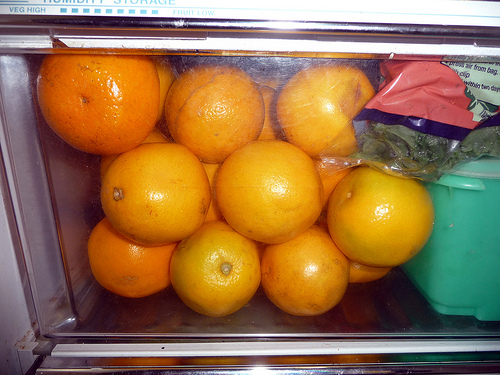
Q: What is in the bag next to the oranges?
A: Greens.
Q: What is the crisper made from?
A: Plastic.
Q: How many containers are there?
A: One.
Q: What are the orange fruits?
A: Oranges.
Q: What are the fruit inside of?
A: A crisper.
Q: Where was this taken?
A: In a fridge.